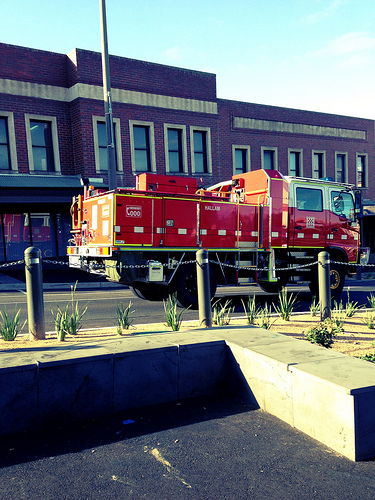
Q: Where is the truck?
A: On the road.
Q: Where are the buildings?
A: Behind the truck.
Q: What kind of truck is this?
A: Fire truck.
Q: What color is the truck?
A: Red.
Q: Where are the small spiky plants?
A: In the ground near the fence.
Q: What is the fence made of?
A: Posts and chains.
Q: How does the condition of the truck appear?
A: New and clean.